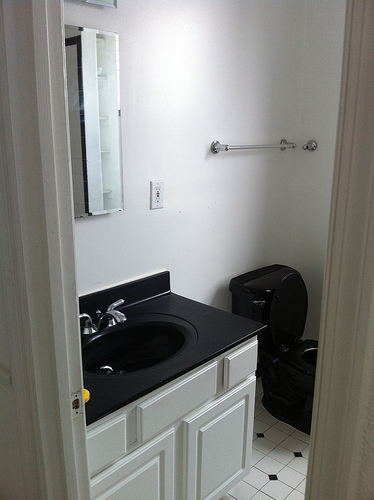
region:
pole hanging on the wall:
[184, 111, 330, 177]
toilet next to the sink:
[222, 248, 345, 451]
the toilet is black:
[222, 243, 327, 444]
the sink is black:
[92, 307, 168, 388]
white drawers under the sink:
[83, 410, 265, 474]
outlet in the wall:
[139, 172, 191, 232]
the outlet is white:
[135, 173, 169, 214]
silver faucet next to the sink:
[75, 297, 132, 326]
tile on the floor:
[265, 462, 283, 473]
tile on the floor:
[267, 448, 288, 460]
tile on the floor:
[247, 471, 263, 482]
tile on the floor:
[274, 449, 285, 457]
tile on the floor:
[255, 438, 268, 451]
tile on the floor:
[287, 440, 301, 451]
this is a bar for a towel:
[206, 128, 306, 159]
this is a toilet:
[229, 249, 323, 433]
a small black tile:
[262, 466, 278, 480]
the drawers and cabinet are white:
[88, 329, 260, 494]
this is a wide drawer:
[124, 357, 221, 436]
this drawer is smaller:
[213, 333, 269, 386]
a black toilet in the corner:
[230, 226, 327, 447]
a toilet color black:
[229, 263, 326, 443]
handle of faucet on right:
[110, 295, 129, 308]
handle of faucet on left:
[78, 306, 92, 330]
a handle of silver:
[211, 133, 301, 158]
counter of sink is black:
[74, 276, 253, 394]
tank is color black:
[229, 256, 314, 371]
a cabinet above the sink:
[63, 23, 129, 220]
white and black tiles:
[242, 416, 308, 490]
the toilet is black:
[228, 261, 345, 445]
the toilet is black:
[225, 265, 321, 450]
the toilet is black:
[228, 245, 322, 473]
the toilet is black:
[216, 266, 325, 435]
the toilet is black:
[225, 262, 311, 468]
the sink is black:
[72, 307, 197, 387]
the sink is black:
[78, 300, 193, 402]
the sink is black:
[74, 296, 209, 409]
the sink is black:
[84, 315, 204, 401]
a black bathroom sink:
[87, 309, 192, 379]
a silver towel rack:
[204, 134, 301, 160]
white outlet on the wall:
[143, 172, 169, 211]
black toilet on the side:
[231, 248, 324, 429]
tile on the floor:
[251, 418, 304, 498]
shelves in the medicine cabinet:
[92, 36, 125, 225]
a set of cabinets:
[100, 387, 262, 498]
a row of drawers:
[62, 336, 266, 470]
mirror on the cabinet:
[63, 25, 110, 225]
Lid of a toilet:
[272, 268, 310, 351]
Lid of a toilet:
[270, 270, 310, 357]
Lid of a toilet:
[265, 272, 309, 358]